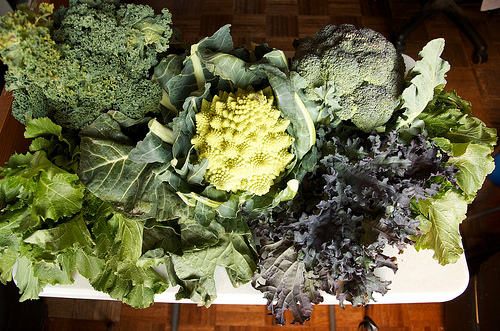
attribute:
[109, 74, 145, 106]
part — green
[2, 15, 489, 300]
table — small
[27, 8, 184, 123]
broccoli — green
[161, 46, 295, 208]
vegtable — yellow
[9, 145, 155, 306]
vegetable — light green, yellow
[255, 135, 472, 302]
vegetable — loose leaf green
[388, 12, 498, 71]
legs — black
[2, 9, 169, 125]
kale — green , yellow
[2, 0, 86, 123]
kale — dry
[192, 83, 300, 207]
cabbage — light green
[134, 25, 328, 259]
leaves — green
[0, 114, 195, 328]
leaves — spinach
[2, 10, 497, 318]
vegetables — green, white, leafy , purple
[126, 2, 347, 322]
broccoli — white 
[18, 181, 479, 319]
tray — white 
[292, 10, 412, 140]
broccoli — Green 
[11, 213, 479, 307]
tray — white 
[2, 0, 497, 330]
table — brown 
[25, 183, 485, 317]
board — white 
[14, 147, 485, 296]
board — white , rounded edge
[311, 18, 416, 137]
broccoli — green 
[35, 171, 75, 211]
line — thin 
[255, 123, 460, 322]
leaves — purpleish 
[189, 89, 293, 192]
vegetable — yellow, textured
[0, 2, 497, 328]
floor — brown, wooden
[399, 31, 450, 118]
leaf — light-shined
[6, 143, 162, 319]
leaves — green, a bunch